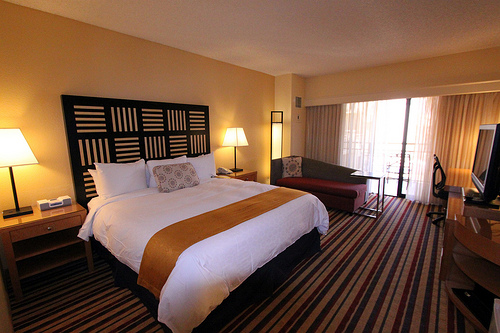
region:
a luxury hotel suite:
[0, 0, 498, 331]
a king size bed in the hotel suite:
[59, 94, 329, 331]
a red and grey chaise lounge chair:
[270, 154, 367, 212]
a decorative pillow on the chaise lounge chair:
[280, 154, 302, 179]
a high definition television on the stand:
[460, 123, 498, 208]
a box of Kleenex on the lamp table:
[35, 193, 72, 210]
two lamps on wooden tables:
[0, 127, 250, 219]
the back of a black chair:
[426, 150, 446, 223]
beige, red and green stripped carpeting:
[296, 266, 438, 331]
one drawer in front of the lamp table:
[10, 215, 82, 242]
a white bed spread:
[85, 152, 330, 324]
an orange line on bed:
[141, 185, 320, 302]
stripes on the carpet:
[339, 249, 415, 322]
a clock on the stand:
[32, 187, 77, 217]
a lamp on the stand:
[0, 121, 40, 224]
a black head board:
[58, 77, 220, 187]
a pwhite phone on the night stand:
[218, 162, 235, 174]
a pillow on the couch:
[278, 153, 306, 176]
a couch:
[266, 149, 365, 207]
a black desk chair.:
[427, 157, 449, 229]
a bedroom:
[6, 16, 495, 331]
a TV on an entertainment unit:
[461, 119, 499, 199]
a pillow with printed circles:
[150, 160, 211, 192]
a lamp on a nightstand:
[219, 117, 258, 171]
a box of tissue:
[36, 190, 76, 210]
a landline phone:
[216, 160, 233, 179]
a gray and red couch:
[278, 152, 371, 199]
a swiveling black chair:
[426, 145, 451, 230]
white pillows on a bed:
[87, 161, 148, 198]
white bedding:
[80, 194, 132, 268]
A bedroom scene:
[0, 4, 495, 321]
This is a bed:
[85, 145, 331, 325]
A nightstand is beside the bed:
[0, 195, 96, 291]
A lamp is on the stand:
[0, 122, 38, 224]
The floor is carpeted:
[333, 237, 419, 314]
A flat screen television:
[463, 114, 498, 213]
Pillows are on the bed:
[87, 151, 214, 196]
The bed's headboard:
[57, 87, 213, 170]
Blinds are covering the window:
[306, 102, 374, 164]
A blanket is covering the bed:
[83, 180, 335, 313]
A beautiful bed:
[53, 83, 336, 328]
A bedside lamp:
[217, 120, 250, 177]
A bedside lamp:
[0, 116, 41, 221]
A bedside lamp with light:
[0, 115, 41, 220]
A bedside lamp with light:
[220, 121, 250, 173]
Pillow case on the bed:
[86, 155, 148, 197]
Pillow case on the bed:
[144, 153, 189, 190]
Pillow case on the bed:
[185, 150, 220, 181]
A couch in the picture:
[268, 155, 382, 215]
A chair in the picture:
[423, 149, 472, 226]